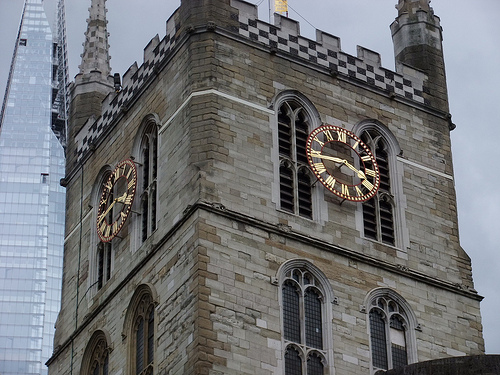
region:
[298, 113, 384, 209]
maroon and gold clock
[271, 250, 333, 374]
large window on a building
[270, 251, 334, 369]
an arched window on a tower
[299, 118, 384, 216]
a clock with golden numbering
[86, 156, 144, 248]
a clock on a tower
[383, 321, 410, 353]
a hole in a window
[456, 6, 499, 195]
a white cloudy sky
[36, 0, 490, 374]
a large building with clocks on the side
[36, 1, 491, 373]
a large stone building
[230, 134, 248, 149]
a rectangular stone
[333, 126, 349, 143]
the 12 on a clock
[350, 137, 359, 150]
the 1 on a clock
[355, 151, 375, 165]
the 2 on a clock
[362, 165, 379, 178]
the 3 on a clock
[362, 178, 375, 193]
the 4 on a clock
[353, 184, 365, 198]
the 5 on a clock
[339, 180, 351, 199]
the 6 on a clock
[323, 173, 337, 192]
the 7 on a clock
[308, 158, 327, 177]
the 8 on a clock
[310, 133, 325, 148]
the 10 on a clock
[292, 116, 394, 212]
clock on a tower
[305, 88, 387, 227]
lighted up clock on tower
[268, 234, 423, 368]
windows of a building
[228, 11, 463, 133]
roof of a building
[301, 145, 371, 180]
hour and minute hand of clock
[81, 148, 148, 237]
clock on a building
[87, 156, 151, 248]
lighted up clock on building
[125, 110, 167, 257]
windows on a building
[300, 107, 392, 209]
roman numerals on a clock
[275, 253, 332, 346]
windows of a tower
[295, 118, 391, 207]
clock on a tower building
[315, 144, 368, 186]
minute and hour hands of clock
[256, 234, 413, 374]
windows on building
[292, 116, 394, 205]
lighted up clock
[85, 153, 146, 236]
analog clock on tower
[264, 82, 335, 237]
windows on a building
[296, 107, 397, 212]
roman numeral on clock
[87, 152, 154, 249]
a lighted up round clock on building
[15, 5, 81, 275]
tall building in the city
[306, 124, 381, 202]
a round clock on the side of a wall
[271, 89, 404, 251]
two arched windows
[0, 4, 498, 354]
a grayish blue sky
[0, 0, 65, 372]
a glass building behind the clock tower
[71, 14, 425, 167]
a checkered design around the top of the tower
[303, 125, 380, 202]
the clock shows 3:44 as the time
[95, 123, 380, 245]
two clocks on a tower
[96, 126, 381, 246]
the clocks have Roman numerals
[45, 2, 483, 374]
a block building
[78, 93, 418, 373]
eight windows on a tower